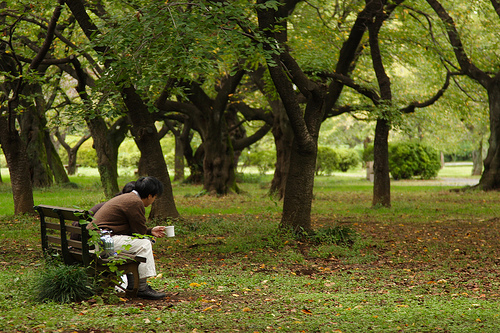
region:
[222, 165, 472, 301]
the ground has fallen leaves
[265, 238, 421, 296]
the ground is brown and green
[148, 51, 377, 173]
this is an orchard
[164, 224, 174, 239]
a white coffee cup held in a man's hand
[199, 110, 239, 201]
an old gnarled tree trunk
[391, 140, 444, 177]
bush next to a distant path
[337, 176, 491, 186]
a walking path through the park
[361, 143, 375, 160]
a person wearing a green coat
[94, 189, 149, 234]
man wearing a brown sweater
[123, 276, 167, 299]
black shoes with brown socks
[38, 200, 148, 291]
a black park bench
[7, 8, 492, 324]
wooden bench in park filled with trees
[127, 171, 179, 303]
man holding white mug in hand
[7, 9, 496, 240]
dark tree trunks with curled branches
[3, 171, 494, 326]
fallen leaves on top of green grass and brown dirt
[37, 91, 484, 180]
row of round bushes behind trees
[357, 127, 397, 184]
man walking next to tree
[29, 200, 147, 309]
small bushy plant in back of bench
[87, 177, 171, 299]
man wearing brown sweater and white pants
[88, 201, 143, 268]
metal thermos on bench next to man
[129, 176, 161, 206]
man with black hair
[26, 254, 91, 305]
bush next to a bench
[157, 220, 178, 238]
man holding a coffee cup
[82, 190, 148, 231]
man wearing a brown sweater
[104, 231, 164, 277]
man wearing white pants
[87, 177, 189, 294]
man sitting on a bench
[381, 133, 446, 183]
bush in the park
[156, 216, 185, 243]
man holding a white cup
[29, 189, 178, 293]
two people sitting on a bench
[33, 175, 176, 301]
Two people sitting on bench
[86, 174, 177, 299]
Man sitting on bench holding white cup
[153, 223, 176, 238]
White mug in man's hand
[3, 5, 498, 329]
Two people sitting on bench among the trees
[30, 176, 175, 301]
Two people having conversation while on bench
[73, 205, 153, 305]
Small plant next to brown bench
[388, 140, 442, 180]
Bush growing in the background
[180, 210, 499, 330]
Small leaves on ground under tree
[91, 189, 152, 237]
Men's long sleeve brown sweater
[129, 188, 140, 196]
White shirt collar around man's neck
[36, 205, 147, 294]
Long wooden park bench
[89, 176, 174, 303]
man sitting drinking coffee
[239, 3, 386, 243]
Large tall brown tree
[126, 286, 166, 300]
Long black leather shoes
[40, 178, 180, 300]
people sitting on a park bench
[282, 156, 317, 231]
the trunk of a tree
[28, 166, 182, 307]
acouple sitting on a bench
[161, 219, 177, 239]
the cup is white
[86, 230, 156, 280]
the pants are white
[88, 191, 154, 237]
the sweter is color brown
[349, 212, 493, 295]
dead leaves on the floor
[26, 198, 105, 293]
the bench is wood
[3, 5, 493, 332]
a couple in a park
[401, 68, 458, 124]
branch of a tree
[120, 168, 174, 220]
man has black hair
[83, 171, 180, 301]
man holds a cup